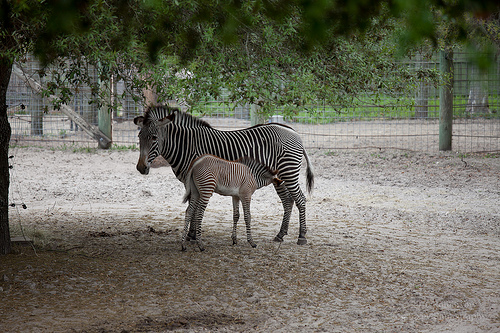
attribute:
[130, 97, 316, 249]
zebra — black, white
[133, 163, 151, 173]
zebra nose — black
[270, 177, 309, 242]
legs — short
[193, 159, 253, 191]
skin — light brown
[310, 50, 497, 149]
fence — metallic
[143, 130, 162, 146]
eye — dark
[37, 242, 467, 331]
sand — brown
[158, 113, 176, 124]
ear — black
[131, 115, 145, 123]
ear — white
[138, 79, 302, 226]
zebra — small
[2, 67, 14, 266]
bark — tree, dark brown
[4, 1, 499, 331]
photo — day time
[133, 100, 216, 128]
hair — black